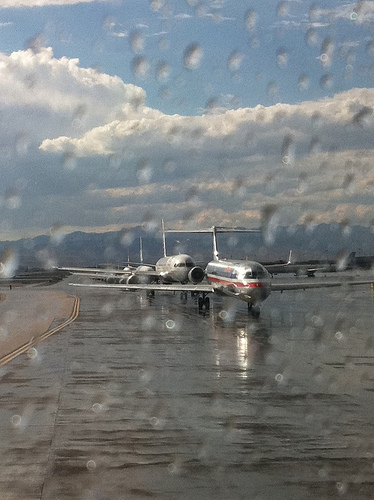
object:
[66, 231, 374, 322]
airplanes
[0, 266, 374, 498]
road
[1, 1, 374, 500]
rain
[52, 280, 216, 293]
line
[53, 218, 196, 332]
airplane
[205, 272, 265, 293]
stripe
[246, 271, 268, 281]
window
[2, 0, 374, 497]
window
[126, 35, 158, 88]
raindrops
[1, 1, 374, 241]
sky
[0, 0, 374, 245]
clouds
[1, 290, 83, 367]
lines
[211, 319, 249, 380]
reflection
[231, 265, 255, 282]
reflection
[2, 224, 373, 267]
mountains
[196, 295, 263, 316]
landing gear